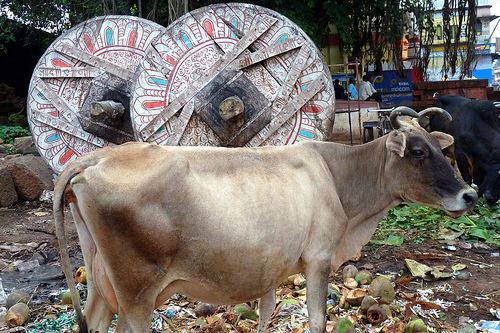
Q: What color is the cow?
A: Brown.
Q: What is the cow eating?
A: Nothing.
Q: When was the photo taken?
A: Daytime.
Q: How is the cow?
A: Standing.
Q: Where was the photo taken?
A: In a field.